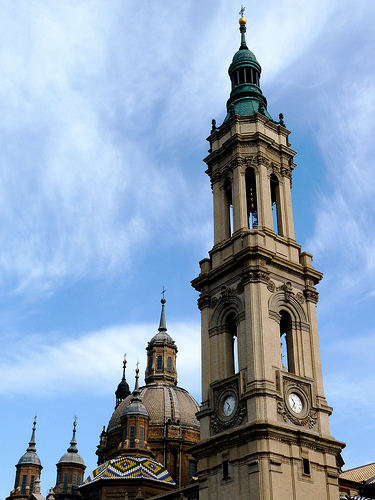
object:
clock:
[288, 390, 304, 411]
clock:
[222, 395, 235, 417]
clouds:
[1, 0, 374, 497]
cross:
[160, 285, 167, 299]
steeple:
[105, 283, 202, 486]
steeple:
[52, 412, 90, 497]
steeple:
[12, 411, 44, 498]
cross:
[73, 413, 78, 422]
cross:
[33, 411, 37, 419]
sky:
[0, 0, 374, 498]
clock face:
[282, 388, 311, 422]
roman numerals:
[299, 402, 303, 407]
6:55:
[282, 387, 309, 419]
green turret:
[229, 46, 263, 91]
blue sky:
[0, 0, 375, 401]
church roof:
[224, 7, 269, 105]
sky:
[3, 4, 366, 270]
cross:
[238, 2, 247, 19]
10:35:
[288, 391, 304, 414]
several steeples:
[6, 287, 196, 495]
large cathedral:
[179, 4, 364, 500]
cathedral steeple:
[227, 9, 272, 104]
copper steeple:
[119, 411, 148, 448]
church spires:
[235, 5, 251, 50]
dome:
[227, 48, 262, 70]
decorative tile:
[83, 458, 175, 482]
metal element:
[255, 72, 258, 86]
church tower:
[186, 2, 345, 498]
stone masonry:
[205, 117, 298, 156]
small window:
[303, 458, 310, 474]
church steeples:
[81, 361, 176, 484]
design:
[80, 450, 177, 484]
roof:
[236, 19, 249, 52]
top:
[231, 18, 252, 51]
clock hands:
[290, 395, 295, 404]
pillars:
[240, 29, 247, 49]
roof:
[115, 379, 131, 399]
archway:
[245, 165, 260, 230]